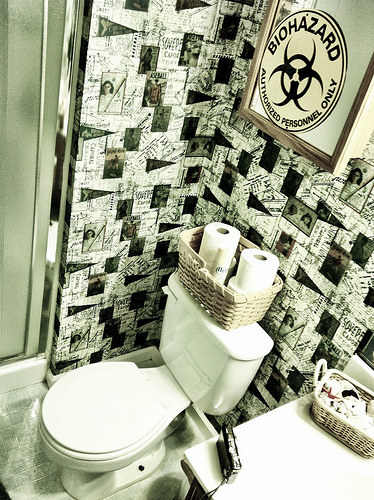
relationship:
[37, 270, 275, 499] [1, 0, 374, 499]
toilet in bathroom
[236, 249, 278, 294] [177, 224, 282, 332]
toilet paper in basket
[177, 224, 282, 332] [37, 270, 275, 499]
basket on toilet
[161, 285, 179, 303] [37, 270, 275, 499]
handle on toilet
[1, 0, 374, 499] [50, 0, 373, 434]
bathroom has wallpaper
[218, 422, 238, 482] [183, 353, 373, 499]
camera on counter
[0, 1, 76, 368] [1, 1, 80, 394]
door to shower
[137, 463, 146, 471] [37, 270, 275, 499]
bolt on toilet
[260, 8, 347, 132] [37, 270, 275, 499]
picture above toilet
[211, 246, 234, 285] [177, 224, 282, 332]
can in basket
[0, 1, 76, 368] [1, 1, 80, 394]
door for shower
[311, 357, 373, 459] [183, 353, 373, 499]
basket on counter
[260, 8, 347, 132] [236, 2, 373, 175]
picture on mirror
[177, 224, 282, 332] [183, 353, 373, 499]
basket on counter